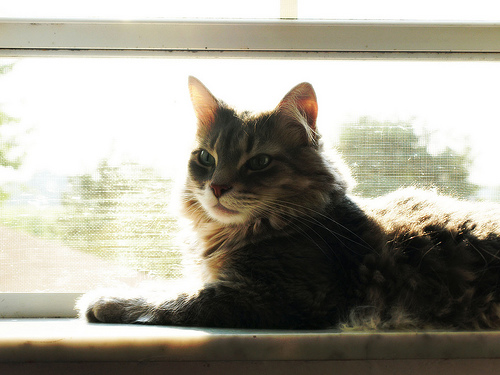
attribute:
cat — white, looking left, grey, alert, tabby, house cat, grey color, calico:
[74, 74, 499, 332]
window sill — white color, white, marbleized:
[0, 316, 498, 365]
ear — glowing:
[273, 80, 319, 129]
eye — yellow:
[247, 154, 272, 170]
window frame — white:
[1, 16, 500, 62]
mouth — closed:
[212, 200, 241, 215]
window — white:
[0, 0, 499, 320]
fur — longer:
[76, 74, 500, 330]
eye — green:
[198, 148, 216, 167]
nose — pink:
[209, 182, 232, 198]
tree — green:
[334, 113, 488, 202]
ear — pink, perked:
[187, 75, 220, 124]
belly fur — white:
[336, 307, 415, 333]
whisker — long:
[261, 196, 369, 246]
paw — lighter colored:
[86, 295, 128, 322]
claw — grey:
[91, 305, 94, 312]